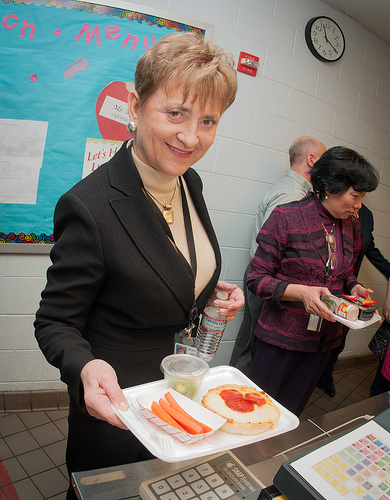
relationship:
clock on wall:
[303, 14, 346, 65] [0, 43, 389, 351]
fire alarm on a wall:
[234, 51, 260, 78] [0, 43, 389, 351]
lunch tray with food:
[108, 363, 303, 465] [133, 352, 281, 447]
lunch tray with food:
[316, 293, 385, 332] [319, 291, 380, 323]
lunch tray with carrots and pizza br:
[108, 363, 303, 465] [133, 352, 281, 447]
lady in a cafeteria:
[33, 30, 247, 498] [0, 1, 389, 500]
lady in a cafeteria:
[242, 145, 380, 421] [0, 1, 389, 500]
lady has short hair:
[33, 30, 247, 498] [133, 33, 239, 116]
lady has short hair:
[242, 145, 380, 421] [308, 146, 380, 205]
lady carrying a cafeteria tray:
[33, 30, 247, 498] [108, 363, 303, 465]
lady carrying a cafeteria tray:
[242, 145, 380, 421] [316, 293, 385, 332]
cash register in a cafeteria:
[137, 407, 389, 499] [0, 1, 389, 500]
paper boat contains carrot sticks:
[134, 385, 230, 446] [150, 391, 212, 436]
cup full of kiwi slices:
[158, 352, 211, 400] [166, 371, 201, 401]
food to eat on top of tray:
[133, 352, 281, 447] [108, 363, 303, 465]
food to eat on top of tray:
[319, 291, 380, 323] [316, 293, 385, 332]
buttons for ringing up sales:
[309, 433, 388, 500] [108, 289, 301, 465]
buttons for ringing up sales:
[309, 433, 388, 500] [316, 293, 385, 332]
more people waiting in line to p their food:
[229, 135, 389, 422] [316, 293, 385, 332]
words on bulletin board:
[0, 14, 159, 178] [0, 1, 216, 254]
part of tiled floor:
[5, 419, 54, 466] [0, 361, 383, 499]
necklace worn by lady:
[141, 182, 178, 229] [33, 30, 247, 498]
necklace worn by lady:
[318, 219, 339, 276] [242, 145, 380, 421]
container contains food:
[158, 352, 211, 400] [166, 371, 201, 401]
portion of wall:
[284, 77, 366, 123] [0, 43, 389, 351]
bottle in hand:
[190, 285, 230, 364] [210, 280, 246, 323]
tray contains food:
[108, 363, 303, 465] [133, 352, 281, 447]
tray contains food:
[316, 293, 385, 332] [319, 291, 380, 323]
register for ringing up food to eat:
[137, 407, 389, 499] [133, 352, 281, 447]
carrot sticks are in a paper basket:
[150, 391, 212, 436] [134, 385, 230, 446]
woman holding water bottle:
[33, 30, 247, 498] [190, 285, 230, 364]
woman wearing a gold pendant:
[33, 30, 247, 498] [162, 203, 175, 225]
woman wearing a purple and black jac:
[242, 145, 380, 421] [242, 193, 364, 356]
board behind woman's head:
[0, 1, 216, 254] [124, 29, 237, 181]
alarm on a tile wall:
[234, 51, 260, 78] [0, 43, 389, 351]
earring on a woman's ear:
[124, 119, 138, 135] [126, 89, 141, 135]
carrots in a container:
[150, 391, 212, 436] [134, 385, 230, 446]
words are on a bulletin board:
[0, 14, 159, 178] [0, 1, 216, 254]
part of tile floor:
[5, 419, 54, 466] [0, 361, 383, 499]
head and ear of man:
[287, 135, 329, 185] [227, 136, 328, 375]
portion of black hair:
[334, 164, 347, 173] [308, 146, 380, 205]